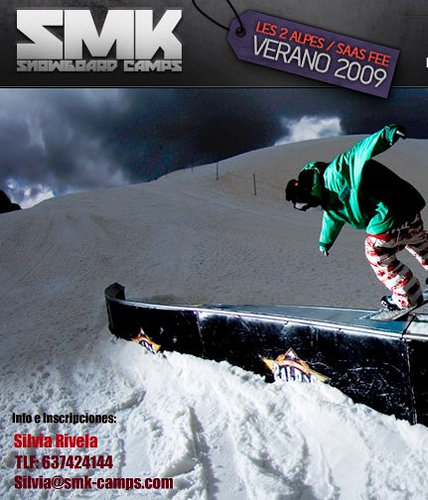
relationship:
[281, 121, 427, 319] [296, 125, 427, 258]
snowboarder wears jacket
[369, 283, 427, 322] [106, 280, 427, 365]
snowboard on rail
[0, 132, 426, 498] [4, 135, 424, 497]
ground covered by snow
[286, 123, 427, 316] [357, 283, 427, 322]
person on snowboard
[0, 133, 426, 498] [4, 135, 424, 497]
hill covered in snow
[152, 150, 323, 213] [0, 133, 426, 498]
fence running beside hill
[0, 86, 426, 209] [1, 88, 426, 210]
clouds in sky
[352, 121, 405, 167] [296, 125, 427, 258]
arm in jacket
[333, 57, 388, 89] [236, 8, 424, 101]
2009 written on tag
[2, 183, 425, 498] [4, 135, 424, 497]
tracks in snow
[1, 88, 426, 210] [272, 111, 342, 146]
sky has cloud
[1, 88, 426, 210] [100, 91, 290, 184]
sky has cloud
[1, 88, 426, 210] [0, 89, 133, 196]
sky has cloud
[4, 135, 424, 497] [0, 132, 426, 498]
snow covering ground